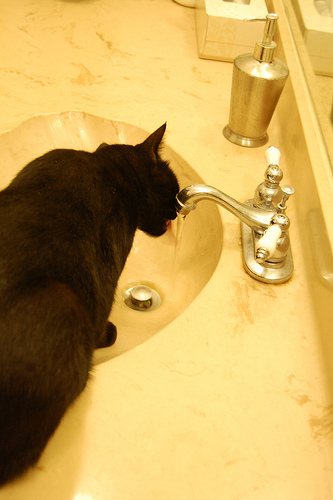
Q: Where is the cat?
A: In a bathroom.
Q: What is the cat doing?
A: Drinking from a faucet.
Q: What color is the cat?
A: Dark brown.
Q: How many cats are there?
A: One.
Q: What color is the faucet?
A: Gold.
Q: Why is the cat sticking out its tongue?
A: To get a drink.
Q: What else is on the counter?
A: A soap dispenser and kleenex.